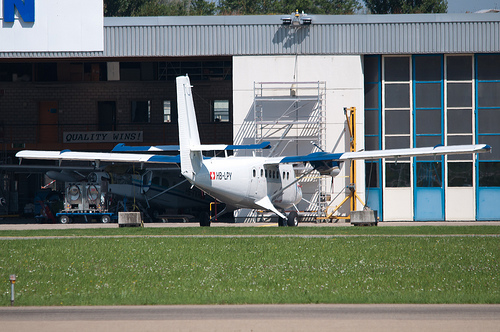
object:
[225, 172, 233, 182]
letter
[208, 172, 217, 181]
print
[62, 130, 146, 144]
banner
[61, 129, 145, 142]
bold print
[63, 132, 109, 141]
quality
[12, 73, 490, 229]
airplane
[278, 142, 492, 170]
aircraft wing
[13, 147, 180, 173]
aircraft wing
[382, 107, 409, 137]
windows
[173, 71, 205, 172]
tail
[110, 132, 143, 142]
print